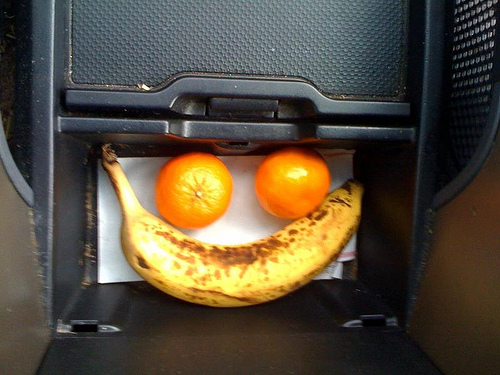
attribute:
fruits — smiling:
[99, 141, 372, 307]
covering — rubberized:
[66, 2, 416, 108]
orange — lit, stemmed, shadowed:
[152, 154, 229, 229]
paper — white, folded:
[101, 155, 351, 294]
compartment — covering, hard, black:
[46, 10, 416, 135]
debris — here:
[80, 171, 109, 294]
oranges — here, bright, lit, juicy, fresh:
[156, 149, 332, 222]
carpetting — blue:
[1, 199, 68, 347]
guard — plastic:
[75, 110, 414, 173]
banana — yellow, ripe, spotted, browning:
[102, 151, 366, 317]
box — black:
[2, 1, 499, 348]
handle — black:
[205, 95, 289, 122]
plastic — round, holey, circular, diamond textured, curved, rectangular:
[2, 0, 498, 215]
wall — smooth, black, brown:
[2, 183, 499, 353]